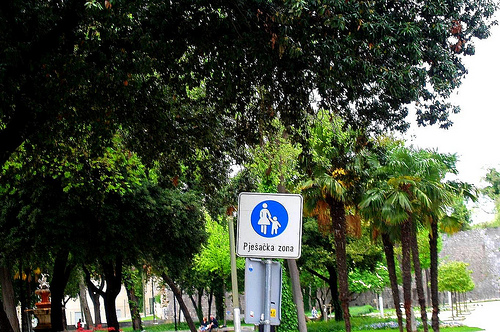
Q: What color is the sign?
A: White.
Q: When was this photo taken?
A: During the day.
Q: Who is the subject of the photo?
A: The sign.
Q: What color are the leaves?
A: Green.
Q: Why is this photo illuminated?
A: Sunlight.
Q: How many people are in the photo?
A: None.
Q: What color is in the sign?
A: Blue.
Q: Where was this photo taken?
A: Near trees.